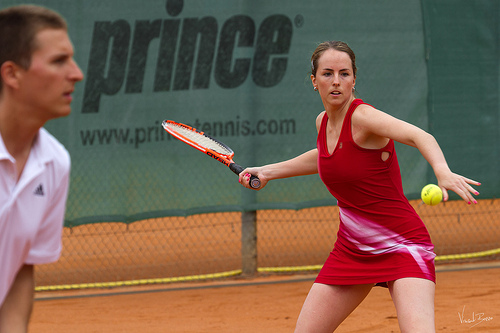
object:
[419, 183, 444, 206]
ball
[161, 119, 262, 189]
racket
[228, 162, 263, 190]
grip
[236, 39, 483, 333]
player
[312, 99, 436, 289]
dress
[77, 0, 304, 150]
ad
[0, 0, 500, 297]
fence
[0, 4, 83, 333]
man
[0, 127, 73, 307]
shirt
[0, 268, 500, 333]
court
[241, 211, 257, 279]
pole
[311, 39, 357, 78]
hair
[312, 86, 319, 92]
earrings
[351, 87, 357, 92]
earrings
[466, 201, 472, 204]
nails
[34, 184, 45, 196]
logo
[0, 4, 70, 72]
hair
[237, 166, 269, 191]
hand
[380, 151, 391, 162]
hole